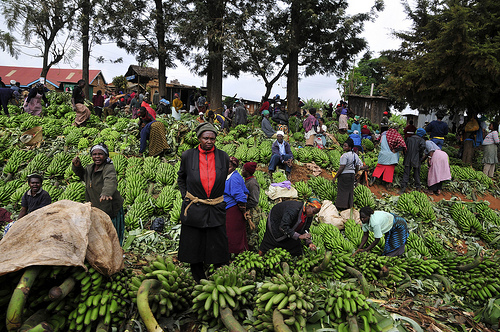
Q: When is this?
A: Daytime.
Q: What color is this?
A: Green.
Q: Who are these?
A: Women.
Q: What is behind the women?
A: House.